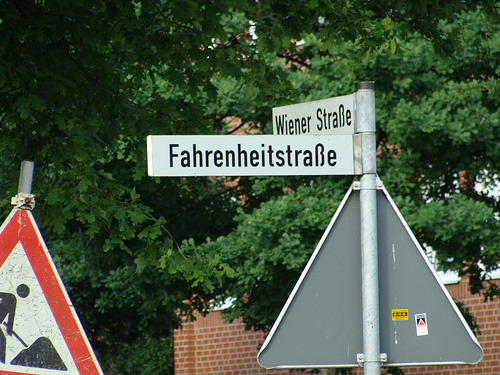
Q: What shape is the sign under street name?
A: Triangle.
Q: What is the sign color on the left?
A: White and red.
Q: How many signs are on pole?
A: Three.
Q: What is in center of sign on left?
A: Black color figure working.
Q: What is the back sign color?
A: Grey.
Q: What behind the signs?
A: Red brick wall.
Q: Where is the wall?
A: Near some trees.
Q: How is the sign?
A: Outlined in red.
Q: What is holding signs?
A: Silver pole.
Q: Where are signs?
A: In the street.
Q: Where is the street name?
A: On the sign.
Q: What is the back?
A: Back of the sign.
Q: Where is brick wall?
A: Behind ign.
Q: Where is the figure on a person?
A: On a sign.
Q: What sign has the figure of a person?
A: Red and white sign.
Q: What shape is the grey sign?
A: Triangle.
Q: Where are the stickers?
A: On the grey sign.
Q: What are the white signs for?
A: Street names.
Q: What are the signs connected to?
A: Silver poles.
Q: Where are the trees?
A: Behind the signs.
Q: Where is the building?
A: Behind the trees.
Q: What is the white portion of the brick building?
A: Windows.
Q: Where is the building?
A: Behind the signs.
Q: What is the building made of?
A: Red bricks.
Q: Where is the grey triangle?
A: On the sign post.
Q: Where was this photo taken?
A: Germany.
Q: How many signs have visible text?
A: Two.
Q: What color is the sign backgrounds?
A: White.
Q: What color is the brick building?
A: Red.